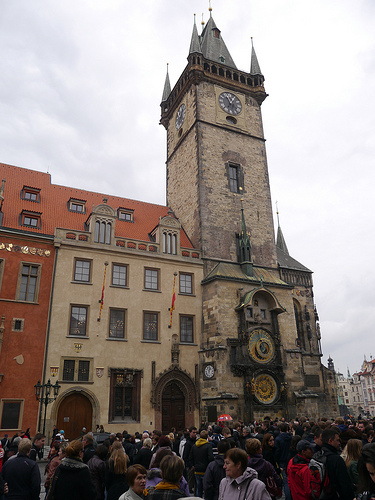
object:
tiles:
[41, 185, 65, 227]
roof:
[0, 161, 198, 259]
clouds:
[9, 31, 77, 109]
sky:
[0, 0, 375, 377]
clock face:
[223, 95, 238, 109]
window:
[143, 266, 161, 292]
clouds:
[35, 48, 141, 150]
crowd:
[0, 413, 375, 499]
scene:
[0, 18, 374, 499]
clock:
[218, 92, 242, 115]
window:
[141, 309, 160, 343]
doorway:
[148, 364, 202, 436]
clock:
[254, 373, 278, 404]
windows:
[111, 262, 129, 286]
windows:
[67, 303, 90, 336]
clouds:
[280, 19, 374, 169]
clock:
[205, 365, 214, 378]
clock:
[248, 329, 275, 364]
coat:
[219, 467, 271, 500]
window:
[70, 199, 85, 212]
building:
[0, 10, 341, 441]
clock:
[175, 104, 186, 130]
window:
[228, 163, 239, 193]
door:
[155, 370, 195, 435]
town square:
[2, 383, 374, 497]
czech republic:
[0, 1, 375, 498]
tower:
[158, 0, 279, 269]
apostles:
[236, 326, 280, 344]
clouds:
[61, 1, 173, 128]